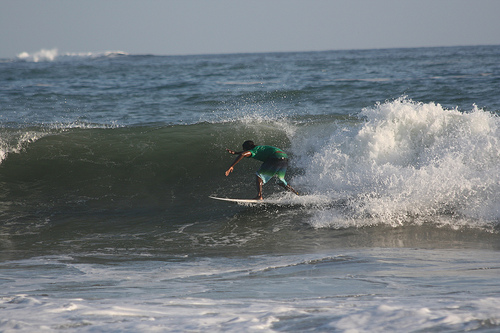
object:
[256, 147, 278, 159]
green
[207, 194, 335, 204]
surfboard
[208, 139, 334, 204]
surfer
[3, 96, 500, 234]
wave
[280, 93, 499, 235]
foam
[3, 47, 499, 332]
water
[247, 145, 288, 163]
shirt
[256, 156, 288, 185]
shorts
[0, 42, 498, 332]
ocean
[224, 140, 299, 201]
boy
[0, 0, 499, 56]
sky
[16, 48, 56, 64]
waves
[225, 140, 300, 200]
surfboarder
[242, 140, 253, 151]
head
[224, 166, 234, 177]
hand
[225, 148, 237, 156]
hand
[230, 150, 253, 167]
arm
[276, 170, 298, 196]
leg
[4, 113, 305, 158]
crest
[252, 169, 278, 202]
legs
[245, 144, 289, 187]
wetsuit